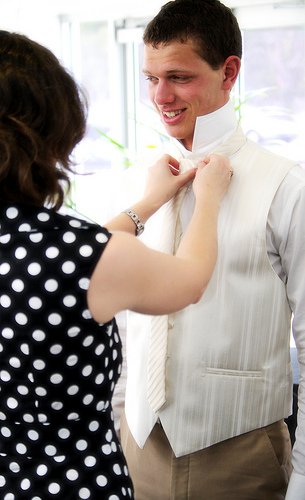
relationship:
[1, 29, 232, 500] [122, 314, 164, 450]
woman tieing tie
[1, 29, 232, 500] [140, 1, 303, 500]
woman helping dress man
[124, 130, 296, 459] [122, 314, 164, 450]
vest and tie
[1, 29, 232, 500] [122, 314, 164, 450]
woman tying tie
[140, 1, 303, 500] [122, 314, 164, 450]
man cannot tie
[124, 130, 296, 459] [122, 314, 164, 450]
vest matches tie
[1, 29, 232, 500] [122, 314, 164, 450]
woman fixing tie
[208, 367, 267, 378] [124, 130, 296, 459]
pocket on vest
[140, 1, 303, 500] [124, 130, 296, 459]
man wearing vest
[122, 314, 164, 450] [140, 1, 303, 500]
tie on man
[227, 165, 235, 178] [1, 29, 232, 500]
ring on woman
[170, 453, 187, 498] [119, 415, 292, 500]
zipper on pant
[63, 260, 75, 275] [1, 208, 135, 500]
dot on dress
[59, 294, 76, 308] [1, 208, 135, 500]
dot on dress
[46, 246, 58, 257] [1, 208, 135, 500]
dot on dress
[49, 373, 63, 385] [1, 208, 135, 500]
dot on dress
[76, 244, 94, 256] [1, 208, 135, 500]
dot on dress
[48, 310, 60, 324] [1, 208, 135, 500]
dot on dress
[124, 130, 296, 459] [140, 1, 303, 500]
vest on man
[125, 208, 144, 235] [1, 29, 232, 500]
watch on woman